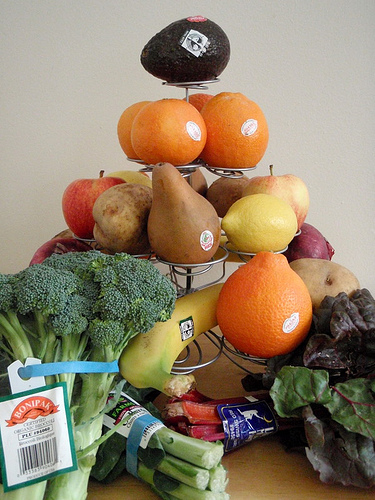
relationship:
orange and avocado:
[132, 97, 208, 165] [140, 15, 232, 82]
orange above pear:
[132, 97, 208, 165] [145, 158, 222, 262]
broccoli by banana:
[2, 247, 179, 499] [121, 284, 225, 398]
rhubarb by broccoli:
[164, 385, 288, 450] [2, 247, 179, 499]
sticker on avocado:
[177, 26, 214, 61] [140, 15, 232, 82]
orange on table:
[132, 97, 208, 165] [80, 304, 373, 498]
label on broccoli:
[0, 383, 78, 491] [2, 247, 179, 499]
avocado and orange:
[140, 15, 232, 82] [132, 97, 208, 165]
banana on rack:
[121, 284, 225, 398] [68, 77, 301, 387]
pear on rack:
[145, 158, 222, 262] [68, 77, 301, 387]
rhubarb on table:
[164, 385, 288, 450] [80, 304, 373, 498]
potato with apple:
[95, 179, 150, 251] [62, 169, 128, 239]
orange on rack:
[132, 97, 208, 165] [68, 77, 301, 387]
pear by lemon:
[145, 158, 222, 262] [218, 194, 297, 252]